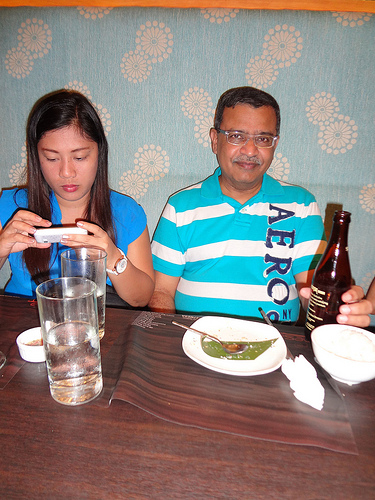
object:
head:
[209, 87, 281, 191]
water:
[40, 321, 103, 408]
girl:
[0, 87, 155, 308]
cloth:
[89, 312, 360, 455]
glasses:
[227, 131, 275, 148]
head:
[36, 90, 99, 201]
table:
[0, 298, 373, 499]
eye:
[228, 130, 243, 143]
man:
[147, 86, 373, 328]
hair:
[213, 85, 280, 134]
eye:
[255, 137, 271, 144]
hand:
[0, 208, 52, 259]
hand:
[61, 221, 114, 262]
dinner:
[181, 315, 285, 379]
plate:
[181, 314, 288, 377]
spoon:
[170, 320, 247, 355]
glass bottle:
[304, 210, 352, 340]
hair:
[23, 87, 116, 285]